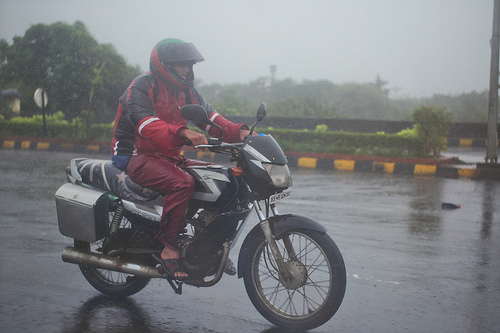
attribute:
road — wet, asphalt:
[1, 146, 499, 331]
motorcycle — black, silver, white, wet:
[53, 104, 348, 330]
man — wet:
[109, 38, 259, 283]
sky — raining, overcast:
[1, 1, 498, 109]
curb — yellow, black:
[1, 129, 500, 178]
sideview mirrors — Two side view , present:
[180, 103, 274, 126]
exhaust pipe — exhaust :
[58, 242, 173, 282]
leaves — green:
[28, 36, 124, 123]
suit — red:
[114, 74, 249, 254]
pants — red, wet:
[115, 151, 230, 256]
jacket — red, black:
[112, 75, 258, 172]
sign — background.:
[31, 81, 49, 113]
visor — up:
[161, 42, 206, 69]